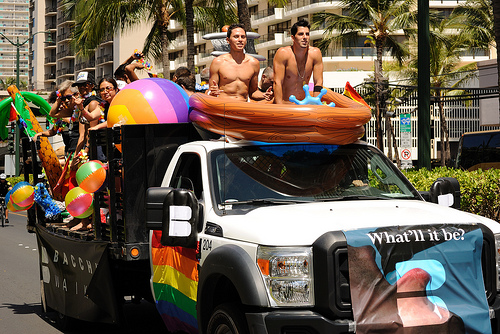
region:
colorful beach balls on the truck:
[64, 162, 107, 223]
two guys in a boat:
[192, 1, 374, 141]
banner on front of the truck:
[350, 229, 483, 332]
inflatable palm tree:
[2, 80, 52, 163]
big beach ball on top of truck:
[105, 74, 191, 124]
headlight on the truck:
[254, 246, 313, 312]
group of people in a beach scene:
[11, 45, 126, 237]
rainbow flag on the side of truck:
[149, 235, 200, 328]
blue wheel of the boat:
[290, 84, 331, 111]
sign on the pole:
[397, 110, 413, 166]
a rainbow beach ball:
[95, 68, 230, 153]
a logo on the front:
[352, 235, 451, 330]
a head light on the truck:
[250, 224, 327, 309]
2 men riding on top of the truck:
[190, 18, 422, 168]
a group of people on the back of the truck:
[13, 48, 158, 208]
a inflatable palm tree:
[7, 73, 91, 207]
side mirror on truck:
[143, 175, 223, 271]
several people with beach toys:
[30, 63, 133, 229]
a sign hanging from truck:
[26, 228, 115, 303]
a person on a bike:
[0, 163, 12, 222]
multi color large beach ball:
[104, 74, 199, 142]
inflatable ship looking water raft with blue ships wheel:
[187, 83, 372, 146]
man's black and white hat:
[68, 69, 98, 90]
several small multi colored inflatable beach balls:
[1, 157, 113, 228]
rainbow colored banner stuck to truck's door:
[142, 223, 224, 330]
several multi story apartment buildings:
[0, 0, 499, 160]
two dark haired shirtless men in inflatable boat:
[182, 16, 372, 147]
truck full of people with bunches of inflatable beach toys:
[13, 18, 498, 332]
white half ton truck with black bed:
[24, 119, 498, 331]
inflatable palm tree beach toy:
[0, 80, 76, 203]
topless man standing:
[261, 17, 341, 111]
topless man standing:
[197, 18, 276, 109]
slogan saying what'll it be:
[354, 224, 469, 248]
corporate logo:
[375, 253, 460, 328]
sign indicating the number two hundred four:
[198, 232, 220, 261]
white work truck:
[10, 102, 497, 331]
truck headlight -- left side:
[254, 224, 327, 319]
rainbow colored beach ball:
[92, 68, 204, 135]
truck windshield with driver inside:
[185, 130, 425, 207]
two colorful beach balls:
[53, 147, 115, 239]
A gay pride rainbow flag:
[142, 225, 206, 317]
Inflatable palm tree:
[5, 83, 63, 186]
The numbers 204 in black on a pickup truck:
[196, 234, 213, 250]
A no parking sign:
[398, 147, 416, 162]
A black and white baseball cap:
[65, 68, 95, 87]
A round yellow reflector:
[123, 245, 142, 263]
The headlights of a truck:
[268, 249, 315, 308]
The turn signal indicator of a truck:
[255, 254, 270, 278]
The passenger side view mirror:
[145, 185, 202, 250]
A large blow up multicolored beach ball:
[97, 72, 197, 151]